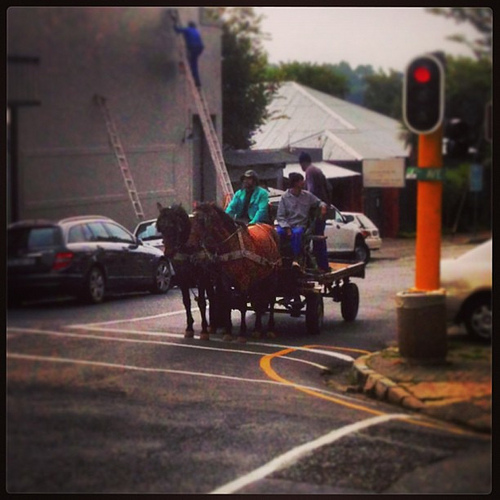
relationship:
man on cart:
[225, 164, 270, 231] [273, 250, 370, 336]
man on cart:
[271, 167, 332, 262] [273, 250, 370, 336]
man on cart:
[297, 150, 335, 273] [273, 250, 370, 336]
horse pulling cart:
[184, 201, 285, 345] [273, 250, 370, 336]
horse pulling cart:
[138, 192, 206, 349] [273, 250, 370, 336]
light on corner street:
[401, 53, 446, 133] [165, 350, 361, 435]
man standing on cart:
[299, 150, 335, 270] [222, 252, 365, 334]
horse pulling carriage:
[184, 201, 285, 345] [273, 236, 367, 333]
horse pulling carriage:
[153, 197, 210, 341] [273, 236, 367, 333]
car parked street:
[3, 212, 173, 305] [0, 252, 496, 496]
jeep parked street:
[322, 207, 369, 264] [0, 252, 496, 496]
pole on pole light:
[413, 127, 444, 292] [403, 55, 445, 135]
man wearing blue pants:
[272, 171, 327, 271] [277, 226, 304, 253]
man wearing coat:
[225, 167, 270, 230] [225, 186, 270, 225]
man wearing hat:
[225, 167, 270, 230] [230, 165, 262, 183]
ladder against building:
[90, 92, 147, 226] [9, 8, 229, 219]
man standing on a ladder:
[174, 15, 207, 100] [178, 40, 238, 221]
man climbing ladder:
[174, 15, 207, 100] [170, 34, 235, 209]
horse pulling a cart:
[152, 199, 295, 349] [222, 252, 365, 334]